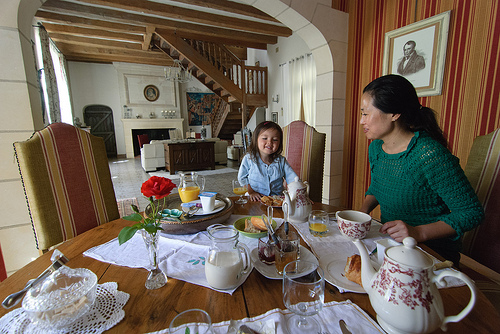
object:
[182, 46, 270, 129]
staircase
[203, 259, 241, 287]
milk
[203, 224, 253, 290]
pitcher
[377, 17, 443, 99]
portrait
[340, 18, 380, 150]
wall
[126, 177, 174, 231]
flower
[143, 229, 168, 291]
vase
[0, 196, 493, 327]
table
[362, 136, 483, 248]
blouse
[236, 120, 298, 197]
kid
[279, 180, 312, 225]
teapot